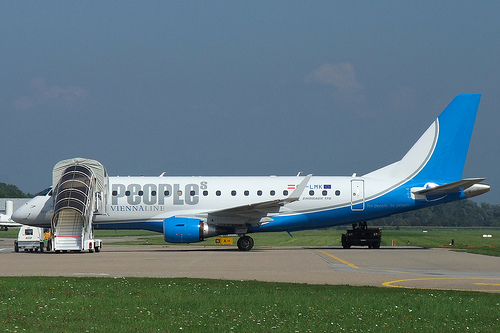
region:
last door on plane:
[348, 178, 365, 211]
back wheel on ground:
[236, 236, 253, 251]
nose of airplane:
[10, 203, 27, 225]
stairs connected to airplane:
[51, 155, 102, 253]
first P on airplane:
[110, 181, 125, 203]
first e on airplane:
[127, 183, 140, 205]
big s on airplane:
[197, 180, 207, 191]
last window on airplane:
[333, 187, 339, 195]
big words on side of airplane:
[110, 180, 210, 205]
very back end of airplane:
[462, 175, 487, 195]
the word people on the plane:
[106, 177, 248, 217]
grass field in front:
[48, 276, 85, 309]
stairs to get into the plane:
[61, 166, 127, 273]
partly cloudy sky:
[88, 47, 375, 167]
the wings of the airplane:
[209, 196, 404, 255]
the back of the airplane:
[399, 68, 496, 203]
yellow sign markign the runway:
[211, 235, 236, 247]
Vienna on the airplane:
[111, 205, 176, 220]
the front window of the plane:
[25, 181, 55, 203]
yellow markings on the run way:
[399, 272, 476, 296]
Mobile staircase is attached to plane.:
[38, 153, 111, 255]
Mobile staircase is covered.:
[48, 152, 108, 253]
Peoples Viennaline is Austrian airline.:
[108, 177, 211, 215]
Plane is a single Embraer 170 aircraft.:
[5, 85, 498, 264]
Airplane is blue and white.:
[6, 87, 498, 269]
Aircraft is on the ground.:
[6, 84, 492, 260]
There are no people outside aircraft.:
[2, 90, 499, 292]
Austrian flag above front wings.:
[285, 180, 300, 191]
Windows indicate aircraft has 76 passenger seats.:
[106, 186, 351, 201]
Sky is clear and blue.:
[1, 1, 498, 209]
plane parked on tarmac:
[7, 87, 489, 264]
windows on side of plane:
[133, 184, 260, 203]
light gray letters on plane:
[108, 178, 201, 210]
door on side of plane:
[339, 170, 371, 217]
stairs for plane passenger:
[49, 197, 92, 254]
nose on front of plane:
[9, 193, 45, 230]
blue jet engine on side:
[159, 210, 199, 246]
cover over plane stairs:
[55, 167, 92, 219]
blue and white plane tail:
[391, 86, 488, 184]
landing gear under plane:
[226, 225, 267, 258]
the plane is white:
[13, 75, 495, 252]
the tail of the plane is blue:
[353, 72, 495, 247]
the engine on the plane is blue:
[158, 212, 207, 242]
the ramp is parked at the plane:
[43, 163, 110, 251]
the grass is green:
[0, 219, 499, 331]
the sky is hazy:
[5, 8, 497, 196]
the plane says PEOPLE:
[108, 182, 205, 212]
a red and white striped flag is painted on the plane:
[286, 183, 298, 192]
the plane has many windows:
[114, 186, 346, 198]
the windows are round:
[113, 182, 346, 199]